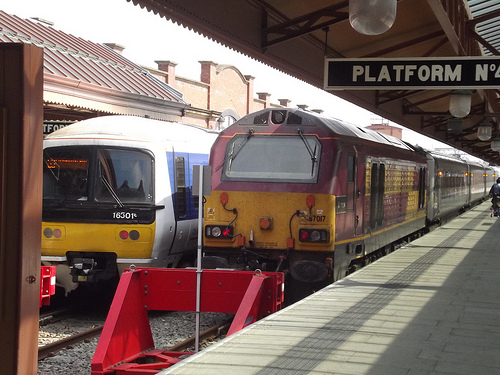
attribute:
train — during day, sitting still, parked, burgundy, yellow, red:
[199, 107, 500, 278]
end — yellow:
[200, 107, 337, 250]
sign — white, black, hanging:
[324, 56, 500, 90]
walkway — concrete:
[155, 196, 499, 374]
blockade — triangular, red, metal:
[91, 269, 286, 374]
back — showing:
[492, 183, 500, 200]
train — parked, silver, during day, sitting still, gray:
[42, 116, 220, 270]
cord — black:
[289, 209, 301, 239]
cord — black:
[221, 204, 240, 227]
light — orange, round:
[304, 194, 317, 212]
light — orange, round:
[219, 192, 229, 209]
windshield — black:
[40, 148, 155, 214]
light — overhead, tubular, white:
[346, 2, 400, 39]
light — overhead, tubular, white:
[447, 91, 472, 123]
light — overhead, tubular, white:
[476, 125, 495, 143]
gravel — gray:
[41, 307, 225, 368]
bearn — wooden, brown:
[0, 41, 44, 374]